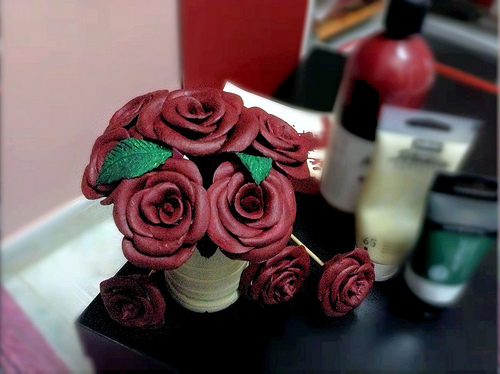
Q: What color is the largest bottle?
A: Red, black, and white.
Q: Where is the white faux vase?
A: Under the flowers.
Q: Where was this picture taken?
A: In front of faux roses.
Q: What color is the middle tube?
A: White.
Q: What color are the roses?
A: Burgundy.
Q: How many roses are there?
A: Nine.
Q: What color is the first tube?
A: Green.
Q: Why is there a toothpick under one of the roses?
A: So it sticks in the faux white vase.